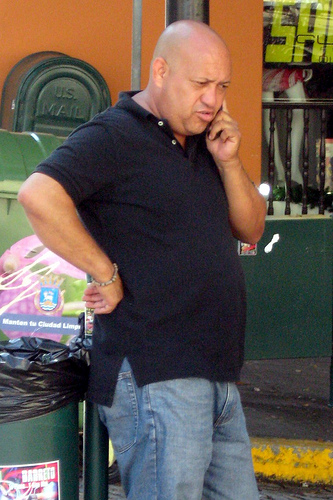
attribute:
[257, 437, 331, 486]
curb — yellow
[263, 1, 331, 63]
sign — yellow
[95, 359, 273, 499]
jeans — faded, blue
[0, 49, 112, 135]
mail box — green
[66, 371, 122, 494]
pole — black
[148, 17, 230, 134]
head — bald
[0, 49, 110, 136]
mailbox — green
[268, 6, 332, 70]
lettering — yellow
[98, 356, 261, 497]
jeans — blue